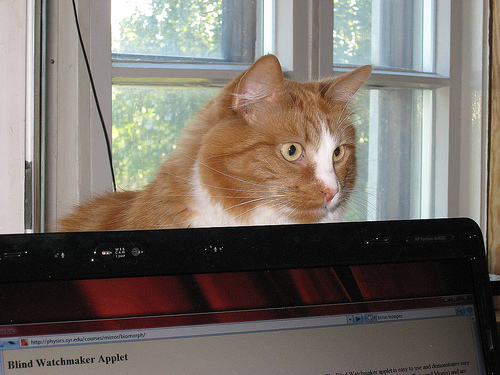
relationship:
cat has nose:
[56, 53, 374, 233] [320, 188, 340, 203]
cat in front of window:
[56, 53, 374, 233] [43, 0, 462, 233]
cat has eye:
[56, 53, 374, 233] [281, 141, 304, 162]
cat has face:
[56, 53, 374, 233] [252, 106, 356, 222]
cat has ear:
[56, 53, 374, 233] [232, 53, 285, 115]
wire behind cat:
[71, 1, 118, 193] [56, 53, 374, 233]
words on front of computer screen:
[9, 352, 129, 370] [0, 259, 488, 374]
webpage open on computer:
[0, 293, 484, 374] [0, 217, 497, 374]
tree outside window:
[113, 0, 370, 222] [43, 0, 462, 233]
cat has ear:
[56, 53, 374, 233] [311, 64, 373, 102]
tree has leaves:
[113, 0, 370, 222] [114, 1, 375, 220]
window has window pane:
[43, 0, 462, 233] [112, 0, 261, 62]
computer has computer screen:
[0, 217, 497, 374] [0, 259, 488, 374]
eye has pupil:
[281, 141, 304, 162] [288, 144, 296, 157]